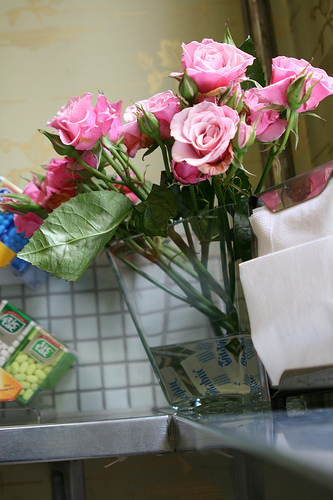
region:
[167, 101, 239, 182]
Pink rose in clear vase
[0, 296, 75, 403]
Plastic case for green and white tic tacs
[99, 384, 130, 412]
One white tile of many on tiled wall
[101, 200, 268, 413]
Clear vase holding pink roses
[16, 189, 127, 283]
Green leaf with along with pink roses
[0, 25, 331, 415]
Roses in a vase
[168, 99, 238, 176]
Pink rose in bloom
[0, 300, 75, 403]
Packages of tic tacs to the left of the vase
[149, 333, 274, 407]
Water in the vase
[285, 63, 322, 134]
Rose bud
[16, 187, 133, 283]
Green leaf in the vase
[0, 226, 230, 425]
Tile on the wall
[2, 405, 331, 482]
Steel counter top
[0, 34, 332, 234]
Pink roses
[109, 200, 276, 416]
Glass vase on the counter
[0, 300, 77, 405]
A double pack of tic tacs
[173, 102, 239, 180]
A pink rose in a bouquet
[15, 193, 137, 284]
A large green leaf on a stem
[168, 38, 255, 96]
A pink rose in a vase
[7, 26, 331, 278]
Many pink roses in a bouqet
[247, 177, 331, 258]
White napkins next to a bouquet of flowers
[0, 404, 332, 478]
A shiny metal counter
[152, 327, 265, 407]
Water in the bottom of a vase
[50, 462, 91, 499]
Metal support post under a counter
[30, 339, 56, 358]
A green label on a tic tac container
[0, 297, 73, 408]
a pack of tick tacs on the table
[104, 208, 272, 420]
a clear glass vase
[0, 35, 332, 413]
a vase with pink roses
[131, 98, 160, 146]
an unopened rose bud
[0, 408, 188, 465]
a stainless steel table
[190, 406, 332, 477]
a reflection on the stainless steel table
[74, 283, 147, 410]
white bathroom tile on the floor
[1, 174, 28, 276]
a container of blue tic tacs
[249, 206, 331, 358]
white hand towels on a rack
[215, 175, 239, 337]
the stem of a rose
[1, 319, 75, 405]
plastic container of yellow tic tacs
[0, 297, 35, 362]
plastic container of white tic tacs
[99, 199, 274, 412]
clear glass flower vase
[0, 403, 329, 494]
stainless steel counter top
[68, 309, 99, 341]
white ceramic tile with gray grout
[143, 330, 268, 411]
clean clear water inside of vase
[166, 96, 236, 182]
light pink rose with one browned petal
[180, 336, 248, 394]
package of flower food magnified by vase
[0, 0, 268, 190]
cream wall with gold accents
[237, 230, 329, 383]
curled white sheet of paper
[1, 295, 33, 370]
container of white tic tacs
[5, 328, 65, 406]
container of yellow tic tacs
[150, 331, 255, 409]
water in the vase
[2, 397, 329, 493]
silver countertop the vase is on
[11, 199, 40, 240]
pink flown on the green stem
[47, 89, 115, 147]
pink flown on the green stem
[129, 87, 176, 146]
pink flown on the green stem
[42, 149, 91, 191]
pink flown on the green stem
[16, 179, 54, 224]
pink flown on the green stem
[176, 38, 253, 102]
pink flown on the green stem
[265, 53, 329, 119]
pink flown on the green stem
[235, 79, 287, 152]
pink flown on the green stem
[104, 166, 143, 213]
pink flown on the green stem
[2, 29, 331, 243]
bouquet of pink roses